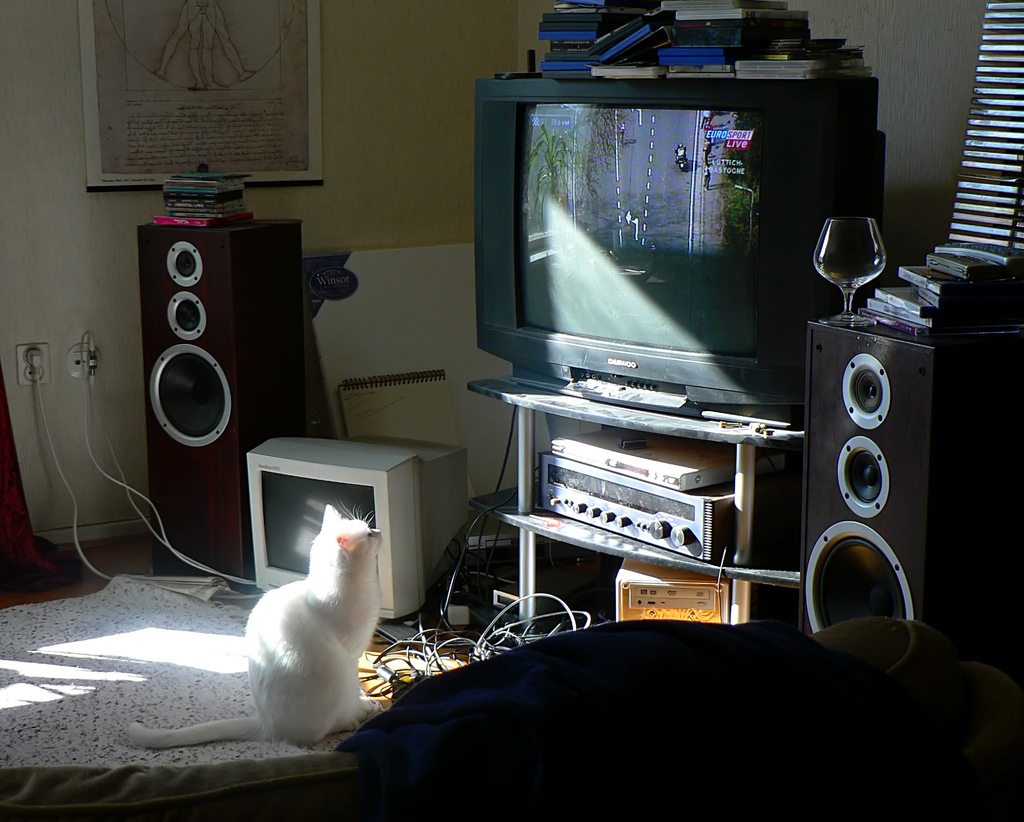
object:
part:
[165, 240, 205, 288]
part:
[165, 289, 209, 342]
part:
[150, 342, 233, 449]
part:
[837, 348, 894, 431]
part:
[831, 431, 892, 522]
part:
[801, 517, 918, 639]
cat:
[128, 499, 385, 751]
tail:
[125, 715, 261, 751]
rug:
[0, 575, 384, 769]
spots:
[0, 659, 9, 672]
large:
[133, 216, 304, 588]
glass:
[809, 214, 890, 329]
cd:
[935, 212, 1012, 264]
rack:
[920, 0, 1024, 302]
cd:
[967, 119, 1024, 133]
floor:
[2, 572, 827, 819]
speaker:
[797, 310, 1021, 676]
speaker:
[133, 214, 309, 579]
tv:
[465, 54, 888, 429]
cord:
[33, 380, 263, 601]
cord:
[483, 575, 595, 655]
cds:
[968, 108, 1024, 122]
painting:
[75, 0, 327, 196]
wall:
[0, 1, 506, 350]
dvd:
[537, 435, 747, 563]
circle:
[147, 342, 233, 449]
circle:
[166, 289, 208, 341]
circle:
[165, 241, 204, 290]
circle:
[800, 517, 917, 636]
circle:
[835, 432, 891, 520]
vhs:
[520, 421, 739, 564]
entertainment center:
[467, 377, 807, 634]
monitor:
[244, 430, 471, 623]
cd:
[955, 173, 1023, 194]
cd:
[948, 229, 1015, 245]